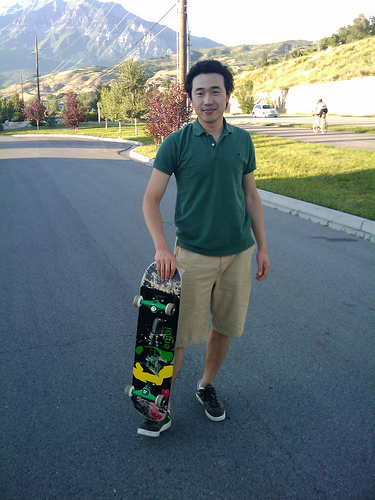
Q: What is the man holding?
A: A skateboard.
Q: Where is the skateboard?
A: On the man's foot.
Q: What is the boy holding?
A: Skateboard.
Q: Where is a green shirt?
A: On the boy.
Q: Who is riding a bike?
A: A man.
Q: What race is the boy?
A: Asian.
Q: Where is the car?
A: On the road.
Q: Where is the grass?
A: In the median.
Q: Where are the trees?
A: On the grass.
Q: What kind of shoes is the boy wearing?
A: Sneakers.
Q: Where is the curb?
A: Next to the street.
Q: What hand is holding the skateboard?
A: Right hand.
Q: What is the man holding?
A: Skateboard.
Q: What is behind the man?
A: Mountains.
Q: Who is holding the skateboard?
A: The man.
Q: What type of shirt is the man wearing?
A: Polo.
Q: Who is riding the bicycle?
A: The person in the background.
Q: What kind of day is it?
A: Sunny.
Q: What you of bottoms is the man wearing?
A: Shorts.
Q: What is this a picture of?
A: A man holding a skateboard.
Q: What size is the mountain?
A: Large.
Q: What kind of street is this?
A: Cul de sac.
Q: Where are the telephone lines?
A: Background.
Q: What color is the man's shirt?
A: Green.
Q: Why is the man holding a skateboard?
A: To pose for the camera.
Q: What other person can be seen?
A: A cyclist.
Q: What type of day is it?
A: A sunny one.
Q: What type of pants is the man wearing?
A: Shorts.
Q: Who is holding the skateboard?
A: The man.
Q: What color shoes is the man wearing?
A: Black.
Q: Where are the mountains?
A: In the background of the picture.